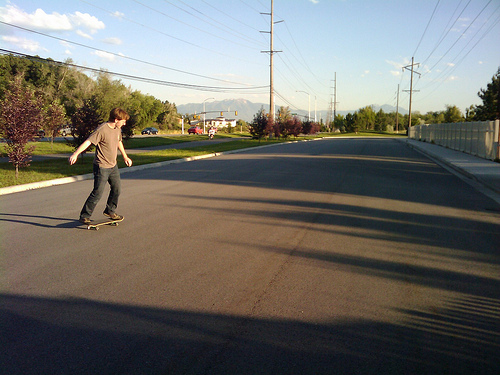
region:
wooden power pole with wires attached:
[239, 6, 303, 141]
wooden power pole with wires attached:
[396, 44, 428, 152]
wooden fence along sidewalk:
[403, 110, 499, 187]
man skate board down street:
[62, 87, 157, 258]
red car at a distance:
[179, 112, 222, 145]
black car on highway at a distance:
[139, 114, 164, 144]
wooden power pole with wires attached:
[323, 52, 355, 139]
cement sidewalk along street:
[394, 132, 497, 231]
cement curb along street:
[143, 137, 250, 169]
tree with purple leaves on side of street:
[4, 80, 65, 195]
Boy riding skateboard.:
[69, 107, 159, 237]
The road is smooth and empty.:
[236, 148, 413, 373]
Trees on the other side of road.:
[8, 79, 85, 174]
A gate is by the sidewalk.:
[443, 115, 498, 147]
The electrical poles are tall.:
[258, 4, 280, 131]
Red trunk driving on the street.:
[185, 122, 207, 142]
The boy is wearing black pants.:
[91, 165, 122, 238]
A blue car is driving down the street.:
[138, 118, 159, 141]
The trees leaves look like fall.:
[250, 111, 322, 141]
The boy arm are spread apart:
[75, 121, 151, 184]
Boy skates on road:
[61, 96, 138, 238]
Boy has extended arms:
[66, 102, 149, 239]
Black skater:
[71, 204, 129, 236]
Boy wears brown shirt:
[65, 100, 140, 232]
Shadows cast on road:
[190, 138, 469, 360]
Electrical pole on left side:
[256, 0, 290, 142]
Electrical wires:
[0, 0, 265, 97]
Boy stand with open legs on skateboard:
[56, 95, 140, 240]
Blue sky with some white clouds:
[11, 7, 486, 79]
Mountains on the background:
[183, 93, 412, 122]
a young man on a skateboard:
[67, 107, 133, 229]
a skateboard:
[79, 214, 125, 231]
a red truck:
[185, 124, 205, 136]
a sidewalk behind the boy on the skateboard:
[0, 135, 254, 164]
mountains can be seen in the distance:
[171, 96, 418, 136]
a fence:
[406, 118, 498, 160]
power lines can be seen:
[384, 0, 499, 137]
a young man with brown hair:
[106, 105, 129, 130]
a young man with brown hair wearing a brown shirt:
[67, 106, 132, 231]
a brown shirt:
[87, 121, 121, 168]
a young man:
[66, 108, 131, 222]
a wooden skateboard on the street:
[78, 213, 124, 230]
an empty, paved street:
[0, 135, 499, 373]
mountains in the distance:
[175, 98, 422, 119]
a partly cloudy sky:
[1, 1, 499, 113]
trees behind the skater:
[0, 51, 180, 175]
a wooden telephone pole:
[258, 0, 283, 124]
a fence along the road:
[408, 117, 499, 162]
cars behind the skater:
[58, 117, 203, 134]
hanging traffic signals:
[193, 109, 240, 121]